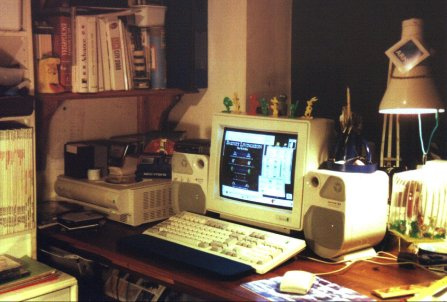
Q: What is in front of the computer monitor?
A: Keyboard.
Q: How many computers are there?
A: One.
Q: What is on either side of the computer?
A: Speakers.